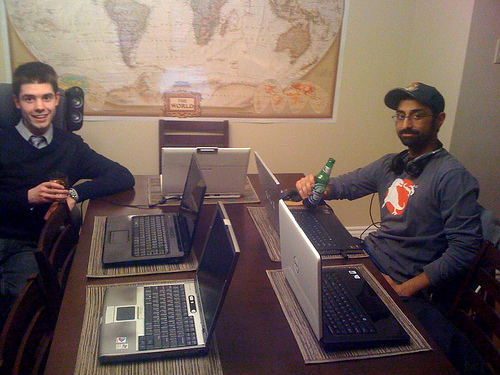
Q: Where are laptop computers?
A: On a table.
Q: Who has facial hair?
A: Man on right.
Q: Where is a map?
A: On the wall.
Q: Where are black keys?
A: On laptop keyboards.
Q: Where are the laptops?
A: On placemats.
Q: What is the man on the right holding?
A: Green bottle.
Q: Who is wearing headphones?
A: Man on the right.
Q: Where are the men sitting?
A: On chairs.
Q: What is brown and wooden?
A: Table.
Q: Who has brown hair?
A: Man on left.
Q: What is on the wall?
A: Map of the world.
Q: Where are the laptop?
A: On desk.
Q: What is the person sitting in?
A: High black chair.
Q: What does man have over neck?
A: Headphones.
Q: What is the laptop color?
A: Silver.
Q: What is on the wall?
A: Poster.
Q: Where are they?
A: In an office.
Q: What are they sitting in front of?
A: Laptops.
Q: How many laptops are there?
A: 5.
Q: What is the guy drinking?
A: Beer.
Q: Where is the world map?
A: On the wall.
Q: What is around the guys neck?
A: Headphones.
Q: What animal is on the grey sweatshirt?
A: Dinosaur.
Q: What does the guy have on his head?
A: Hat.